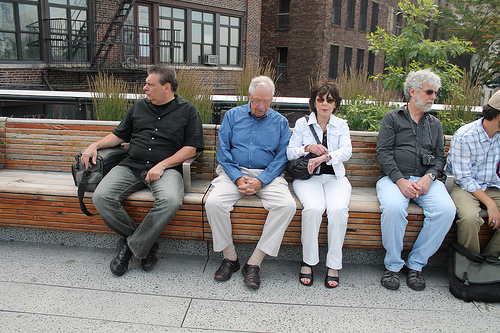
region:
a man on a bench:
[94, 64, 199, 285]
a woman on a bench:
[292, 73, 352, 290]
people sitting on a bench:
[77, 71, 499, 286]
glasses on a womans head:
[309, 94, 344, 107]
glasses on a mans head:
[414, 82, 441, 97]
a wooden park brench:
[16, 116, 71, 218]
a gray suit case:
[65, 135, 120, 200]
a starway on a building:
[41, 9, 157, 75]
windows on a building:
[184, 14, 246, 62]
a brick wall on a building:
[292, 2, 334, 61]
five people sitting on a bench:
[71, 49, 498, 271]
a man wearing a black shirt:
[131, 59, 181, 170]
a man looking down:
[238, 64, 275, 139]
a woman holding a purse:
[290, 76, 349, 197]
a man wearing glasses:
[394, 65, 445, 132]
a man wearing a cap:
[486, 83, 498, 120]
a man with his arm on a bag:
[63, 64, 171, 194]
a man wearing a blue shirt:
[229, 77, 275, 172]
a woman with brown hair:
[304, 74, 343, 121]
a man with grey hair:
[403, 50, 454, 126]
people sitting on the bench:
[113, 67, 490, 260]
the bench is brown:
[10, 110, 67, 224]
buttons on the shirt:
[152, 113, 164, 133]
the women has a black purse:
[290, 153, 305, 175]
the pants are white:
[299, 190, 344, 261]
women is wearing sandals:
[300, 262, 319, 288]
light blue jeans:
[380, 192, 405, 242]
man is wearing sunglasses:
[417, 87, 437, 99]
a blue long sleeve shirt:
[227, 116, 251, 153]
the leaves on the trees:
[374, 28, 429, 65]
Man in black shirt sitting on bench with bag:
[71, 61, 205, 276]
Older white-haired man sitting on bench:
[203, 74, 298, 289]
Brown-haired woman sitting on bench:
[285, 78, 354, 290]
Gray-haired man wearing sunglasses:
[373, 68, 457, 293]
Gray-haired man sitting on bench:
[373, 65, 457, 292]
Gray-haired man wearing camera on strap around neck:
[373, 67, 456, 292]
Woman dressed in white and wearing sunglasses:
[286, 77, 355, 289]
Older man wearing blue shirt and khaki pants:
[203, 73, 298, 290]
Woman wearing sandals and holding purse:
[286, 79, 353, 289]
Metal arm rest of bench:
[181, 150, 198, 195]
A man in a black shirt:
[71, 55, 211, 275]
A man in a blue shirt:
[192, 68, 299, 288]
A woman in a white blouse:
[286, 81, 363, 290]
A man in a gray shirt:
[367, 68, 452, 293]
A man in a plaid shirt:
[446, 93, 499, 298]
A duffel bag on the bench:
[66, 140, 136, 223]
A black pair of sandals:
[298, 258, 345, 293]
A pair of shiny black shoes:
[103, 233, 171, 280]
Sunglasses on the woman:
[316, 93, 336, 105]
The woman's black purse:
[283, 111, 331, 182]